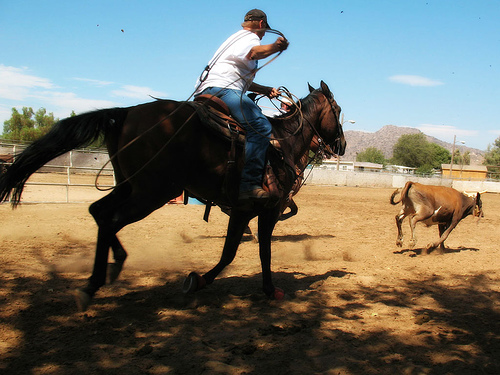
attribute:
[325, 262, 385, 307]
dirt — brown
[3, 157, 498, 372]
dirt — brown 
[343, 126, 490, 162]
hill — brown, rocky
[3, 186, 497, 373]
dirt — brown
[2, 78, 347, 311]
horse — brown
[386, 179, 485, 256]
cow — small, brown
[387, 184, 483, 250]
cow — brown, running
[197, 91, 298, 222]
saddle — brown, leather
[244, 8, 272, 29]
cap — black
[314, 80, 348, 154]
head — horse's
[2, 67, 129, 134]
clouds — white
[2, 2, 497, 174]
sky — blue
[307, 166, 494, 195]
fence — white, wooden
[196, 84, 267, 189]
jeans — blue